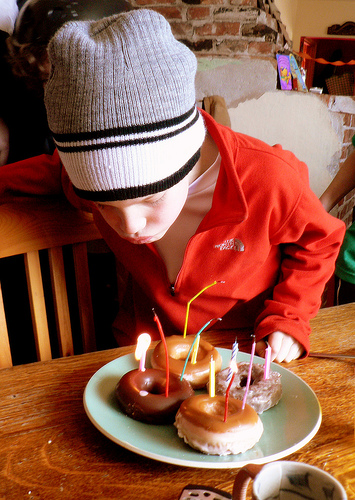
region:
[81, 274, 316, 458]
plate of doughnuts decorated with candles for dessert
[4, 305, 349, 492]
blue plate on brown wooden table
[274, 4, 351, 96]
cards and red twisted streamer in corner of room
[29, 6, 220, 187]
a grey knit hat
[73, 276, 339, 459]
plate of doughnuts with candles on them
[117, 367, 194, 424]
a chocolated glazed doughnut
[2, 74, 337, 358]
boy in a red pull over shirt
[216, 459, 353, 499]
top of a mug on the table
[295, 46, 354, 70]
orange streamers decorating the room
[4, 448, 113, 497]
brown wooden table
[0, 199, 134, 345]
brown slatted back of wooden chair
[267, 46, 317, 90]
Birthday cards on ledge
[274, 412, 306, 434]
a plate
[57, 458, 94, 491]
a table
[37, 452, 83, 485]
the table is brown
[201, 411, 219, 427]
the icing is brown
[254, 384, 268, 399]
icing on the donut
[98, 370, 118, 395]
shadow on the plate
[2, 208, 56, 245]
the back of the chair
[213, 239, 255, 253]
logo on the sweater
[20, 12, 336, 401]
this is a boy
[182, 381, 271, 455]
this is a doughnut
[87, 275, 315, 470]
a plate of doughnuts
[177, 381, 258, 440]
icing on a doughnut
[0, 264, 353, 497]
this is a wooden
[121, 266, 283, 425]
candles on the doughnuts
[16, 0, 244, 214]
boy wearing a hat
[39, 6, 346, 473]
Boy blowing out candles on doughnuts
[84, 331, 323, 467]
Four doughnuts on a plate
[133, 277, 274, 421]
Candles on the four doughnuts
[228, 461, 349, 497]
Coffee mug by the plate of doughnuts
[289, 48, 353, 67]
Streamer in the background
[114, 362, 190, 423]
Chocolate frosted doughnut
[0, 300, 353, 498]
Wooden table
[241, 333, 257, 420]
Long pink candle on the doughnut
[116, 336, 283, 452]
four donuts on a plate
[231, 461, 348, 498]
coffee mug near the plate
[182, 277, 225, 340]
something that is not a candle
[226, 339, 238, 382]
a blue and white striped candle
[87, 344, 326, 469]
a plate made for dining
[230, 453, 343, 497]
a vessel made for drinking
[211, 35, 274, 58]
a brick in a wall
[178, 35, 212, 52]
a brick in a wall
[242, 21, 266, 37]
a brick in a wall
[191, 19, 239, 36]
a brick in a wall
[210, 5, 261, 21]
a brick in a wall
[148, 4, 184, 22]
a brick in a wall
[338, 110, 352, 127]
a brick in a wall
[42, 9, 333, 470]
A child in red blowing out candles on doughnuts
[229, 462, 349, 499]
An empty coffee mug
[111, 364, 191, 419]
A chocolate covered doughnut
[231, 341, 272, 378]
Birthday candles on a doughnut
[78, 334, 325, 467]
A white plate full of doughnuts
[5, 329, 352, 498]
A brown wooden table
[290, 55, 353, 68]
A red paper banner